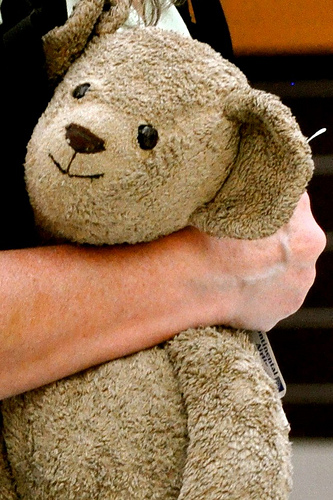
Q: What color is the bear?
A: Brown.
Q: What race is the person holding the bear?
A: Caucasian.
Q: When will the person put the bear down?
A: After they have finished holding it.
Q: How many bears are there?
A: One.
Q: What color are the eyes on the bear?
A: Black.